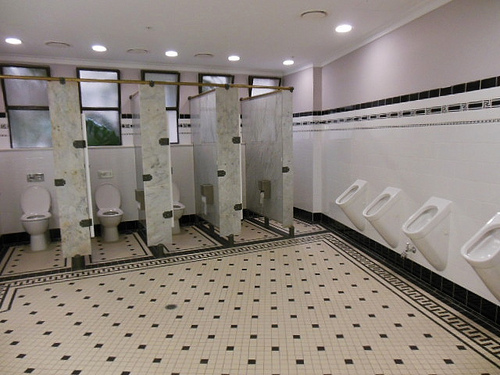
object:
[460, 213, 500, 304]
urinal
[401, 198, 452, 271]
urinal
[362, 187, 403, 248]
urinal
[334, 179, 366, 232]
urinal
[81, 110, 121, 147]
window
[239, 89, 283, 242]
stalls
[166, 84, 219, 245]
stalls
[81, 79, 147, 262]
stalls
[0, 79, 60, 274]
stalls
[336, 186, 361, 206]
urinal bowl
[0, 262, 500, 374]
floor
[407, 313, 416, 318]
tile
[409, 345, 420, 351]
tile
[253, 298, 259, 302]
tile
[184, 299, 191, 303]
tile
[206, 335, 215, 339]
tile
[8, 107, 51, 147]
glass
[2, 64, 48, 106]
glass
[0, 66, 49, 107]
window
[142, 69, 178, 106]
window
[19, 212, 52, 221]
toilet seat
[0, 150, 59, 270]
porcelin toilets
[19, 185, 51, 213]
lid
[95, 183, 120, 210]
lid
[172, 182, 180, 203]
lid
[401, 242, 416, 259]
water line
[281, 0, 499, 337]
wall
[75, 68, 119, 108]
window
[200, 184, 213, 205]
dispensers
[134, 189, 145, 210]
dispensers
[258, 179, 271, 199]
dispensers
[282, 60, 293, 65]
lights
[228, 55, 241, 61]
lights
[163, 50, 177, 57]
lights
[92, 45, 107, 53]
lights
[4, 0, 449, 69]
ceiling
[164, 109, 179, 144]
window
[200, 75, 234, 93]
window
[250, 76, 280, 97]
window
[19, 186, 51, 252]
kemode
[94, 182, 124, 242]
kemode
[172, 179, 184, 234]
kemode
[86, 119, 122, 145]
bush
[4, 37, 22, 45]
lights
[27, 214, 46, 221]
bowl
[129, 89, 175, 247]
marble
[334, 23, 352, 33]
lights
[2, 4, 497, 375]
bathroom